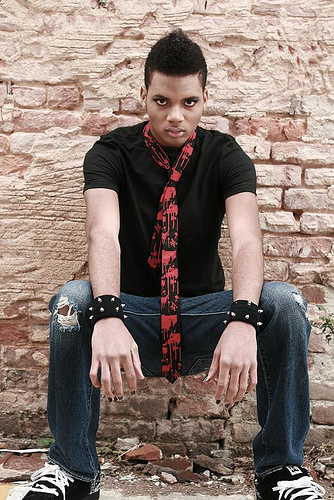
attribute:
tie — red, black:
[146, 118, 191, 381]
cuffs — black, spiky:
[223, 296, 263, 326]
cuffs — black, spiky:
[83, 287, 126, 324]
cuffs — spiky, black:
[220, 298, 271, 327]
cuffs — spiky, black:
[84, 291, 130, 323]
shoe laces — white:
[23, 462, 70, 499]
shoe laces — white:
[270, 475, 328, 498]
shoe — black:
[252, 463, 320, 498]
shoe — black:
[21, 456, 98, 498]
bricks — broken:
[115, 437, 234, 498]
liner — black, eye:
[180, 96, 196, 107]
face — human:
[142, 65, 201, 142]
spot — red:
[158, 361, 169, 374]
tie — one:
[142, 133, 183, 383]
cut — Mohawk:
[149, 29, 202, 75]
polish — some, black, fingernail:
[211, 392, 243, 407]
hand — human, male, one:
[210, 317, 262, 415]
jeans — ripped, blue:
[51, 277, 316, 478]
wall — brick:
[235, 49, 320, 163]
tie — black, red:
[146, 142, 189, 379]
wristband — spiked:
[85, 287, 127, 322]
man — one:
[49, 27, 318, 498]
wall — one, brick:
[240, 33, 317, 162]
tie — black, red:
[140, 124, 198, 382]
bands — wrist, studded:
[80, 289, 269, 330]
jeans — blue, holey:
[33, 266, 316, 480]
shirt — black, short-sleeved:
[81, 122, 252, 302]